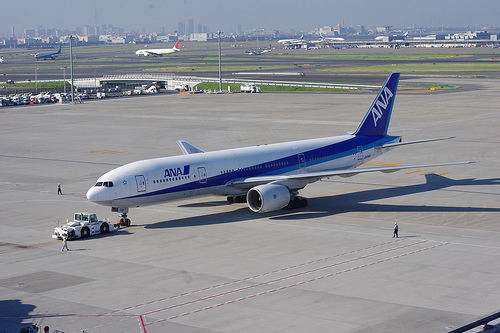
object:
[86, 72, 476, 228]
plane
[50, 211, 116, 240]
vehicle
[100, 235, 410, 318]
lines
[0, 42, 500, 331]
ground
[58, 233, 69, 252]
man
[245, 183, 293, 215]
engine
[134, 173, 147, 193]
door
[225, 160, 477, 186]
wing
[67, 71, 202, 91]
bridge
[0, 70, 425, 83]
runway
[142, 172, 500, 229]
shadow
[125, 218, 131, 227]
tires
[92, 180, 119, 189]
cockpit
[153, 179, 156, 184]
windows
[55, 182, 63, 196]
person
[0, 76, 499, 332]
tarmac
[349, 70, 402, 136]
tail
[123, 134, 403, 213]
fuselage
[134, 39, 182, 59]
airplanes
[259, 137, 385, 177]
stripes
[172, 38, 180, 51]
tail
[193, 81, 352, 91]
grass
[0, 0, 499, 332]
background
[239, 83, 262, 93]
vehicles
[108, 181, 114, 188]
windows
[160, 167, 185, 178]
ana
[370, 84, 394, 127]
ana